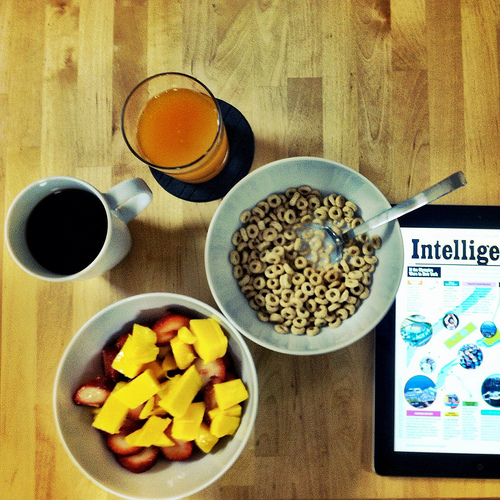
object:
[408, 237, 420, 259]
print letter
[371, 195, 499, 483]
box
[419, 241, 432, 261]
print letter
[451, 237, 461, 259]
print letter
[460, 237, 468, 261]
print letter